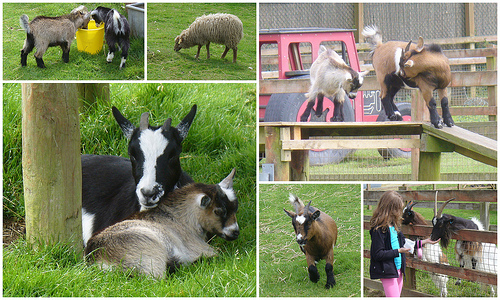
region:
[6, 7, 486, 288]
Six different photos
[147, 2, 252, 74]
One sheep in the photo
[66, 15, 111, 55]
Yellow bucket in the photo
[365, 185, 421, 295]
One girl in the photo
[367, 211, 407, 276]
Black coat on the girl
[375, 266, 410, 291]
Pink pants on the girl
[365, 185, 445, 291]
Girl feeding a goat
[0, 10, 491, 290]
Photos taken at farms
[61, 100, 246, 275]
Two goats lying in the grass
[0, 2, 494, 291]
All photos taken during the day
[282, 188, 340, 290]
a brown and white goat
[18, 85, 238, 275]
a couple of goats by a post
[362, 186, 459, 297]
a girl feeding a goat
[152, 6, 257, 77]
a lamb eating grass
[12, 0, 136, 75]
goats drinking water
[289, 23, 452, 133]
goats on a railing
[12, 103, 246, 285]
goats lying in a grassy area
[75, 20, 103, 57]
a yellow bucket of water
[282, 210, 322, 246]
a brown and white goats head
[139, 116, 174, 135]
gray horns on a goat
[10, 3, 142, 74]
this is two dogs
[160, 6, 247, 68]
the sheep is dirty white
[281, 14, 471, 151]
the animals are on a board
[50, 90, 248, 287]
the animals are cuddling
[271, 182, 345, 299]
the animal is standing in grass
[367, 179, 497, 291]
the girl is feeding the goat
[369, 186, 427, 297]
the girl has brown hair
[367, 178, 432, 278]
the girl has straight hair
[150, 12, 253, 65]
the sheep is in grass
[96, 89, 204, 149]
the goat has horns on his head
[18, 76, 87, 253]
wooden pole in ground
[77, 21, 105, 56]
yellow bucket on ground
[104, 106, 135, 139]
black ear on the right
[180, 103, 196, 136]
left ear on animal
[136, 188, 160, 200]
the nose on the animal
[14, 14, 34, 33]
tail on the animal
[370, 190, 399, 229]
hair on the girl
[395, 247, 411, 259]
right hand on woman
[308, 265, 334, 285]
front feet on animals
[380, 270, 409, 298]
pink pants on girl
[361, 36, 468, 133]
the goat is brown in color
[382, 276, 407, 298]
the pants are pink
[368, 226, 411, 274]
the jacket is black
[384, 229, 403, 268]
the shirt is blue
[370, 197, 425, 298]
the girl is feeding the goat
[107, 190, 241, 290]
the goat is brown and white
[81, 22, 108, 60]
the bucket is yellow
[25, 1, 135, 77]
the goats are drinking from the bucket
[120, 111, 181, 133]
horns are on the head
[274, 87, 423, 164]
tires are in the background